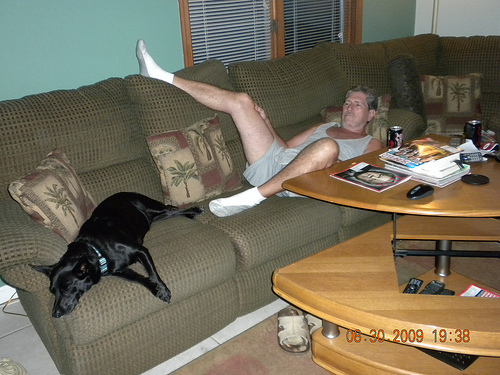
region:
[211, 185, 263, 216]
The man is wearing socks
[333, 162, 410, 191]
A magazine on the table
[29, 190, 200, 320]
A dog on the couch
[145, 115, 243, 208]
A pillow on the couch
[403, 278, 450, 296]
Remote controls on the table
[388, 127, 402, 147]
A soda can on the table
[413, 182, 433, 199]
A computer mouse by the magazine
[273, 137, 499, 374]
A table by the couch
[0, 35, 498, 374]
A couch by the window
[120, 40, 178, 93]
socks of the person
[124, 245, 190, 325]
legs of the dog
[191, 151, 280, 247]
leg of the man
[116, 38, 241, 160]
a leg of man raising up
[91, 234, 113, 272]
belt tied to dog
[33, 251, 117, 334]
face of the dog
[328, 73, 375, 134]
face of the man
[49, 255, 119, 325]
dog sleeping in sofa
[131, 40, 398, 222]
man lying on a couch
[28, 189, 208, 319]
dog on a couch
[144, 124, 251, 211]
pillow on a couch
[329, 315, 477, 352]
date and time of photo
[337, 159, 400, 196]
magazine on a table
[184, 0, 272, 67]
blinds on a window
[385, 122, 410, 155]
can of a drink on table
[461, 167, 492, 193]
coaster on a table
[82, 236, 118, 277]
collar on a dog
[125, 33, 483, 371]
the man is lying down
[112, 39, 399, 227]
the man has his leg propped up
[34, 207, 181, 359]
the dog is asleep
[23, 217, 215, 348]
the dog is lying down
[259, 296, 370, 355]
the man's shoes are on the floor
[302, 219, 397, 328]
the table is made of wood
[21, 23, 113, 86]
the wall is mint green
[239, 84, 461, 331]
the man is wearing gray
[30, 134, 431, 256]
pillows are on the couch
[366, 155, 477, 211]
magazines are on the table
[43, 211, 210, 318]
dog sleeping on couch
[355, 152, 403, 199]
man laying on couch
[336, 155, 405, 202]
magazine on table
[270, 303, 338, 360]
shoe on floor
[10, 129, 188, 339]
dog laying against a pillow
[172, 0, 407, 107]
window behind couch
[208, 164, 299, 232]
sock on man's foot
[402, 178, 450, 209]
mouse on table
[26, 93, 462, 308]
man and dog on couch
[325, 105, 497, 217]
Table with magazines on top of it